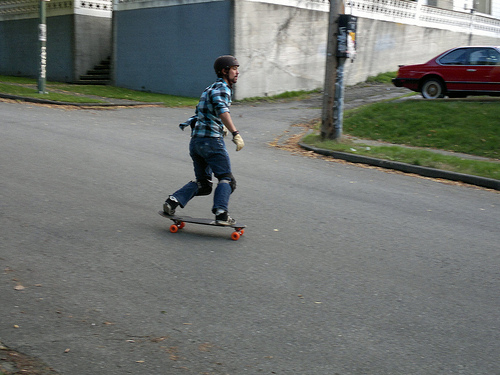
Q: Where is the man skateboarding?
A: On the street.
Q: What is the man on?
A: Skateboard.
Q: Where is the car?
A: Parked.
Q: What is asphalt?
A: Street.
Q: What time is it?
A: Afternoon.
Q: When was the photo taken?
A: During the daytime.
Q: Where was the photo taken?
A: Outside somewhere.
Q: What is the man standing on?
A: The skateboard.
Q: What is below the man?
A: The street.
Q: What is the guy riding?
A: The skateboard.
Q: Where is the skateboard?
A: On the street.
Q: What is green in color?
A: The grass.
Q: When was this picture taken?
A: Daytime.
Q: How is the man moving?
A: He's riding a skateboard.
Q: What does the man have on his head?
A: A Helmet.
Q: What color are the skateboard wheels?
A: Orange.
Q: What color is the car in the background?
A: Red.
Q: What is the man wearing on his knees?
A: Safety-pads.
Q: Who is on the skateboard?
A: A man.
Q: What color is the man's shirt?
A: Blue.